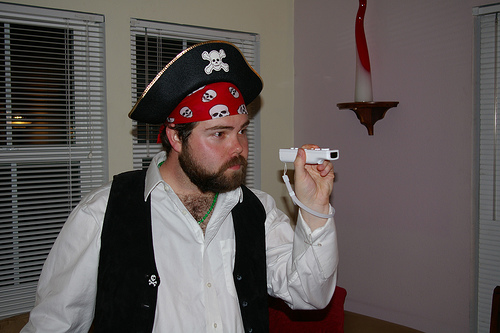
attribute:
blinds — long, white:
[12, 13, 124, 280]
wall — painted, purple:
[292, 13, 474, 330]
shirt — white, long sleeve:
[40, 166, 379, 322]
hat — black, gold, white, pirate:
[129, 41, 278, 127]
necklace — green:
[165, 180, 232, 257]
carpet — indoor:
[319, 297, 387, 330]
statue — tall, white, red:
[327, 10, 411, 132]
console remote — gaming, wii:
[268, 147, 343, 167]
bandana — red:
[141, 70, 270, 146]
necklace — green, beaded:
[170, 186, 231, 246]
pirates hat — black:
[129, 37, 262, 125]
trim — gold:
[126, 38, 261, 116]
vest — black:
[90, 168, 267, 331]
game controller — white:
[278, 142, 341, 165]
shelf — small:
[338, 97, 401, 137]